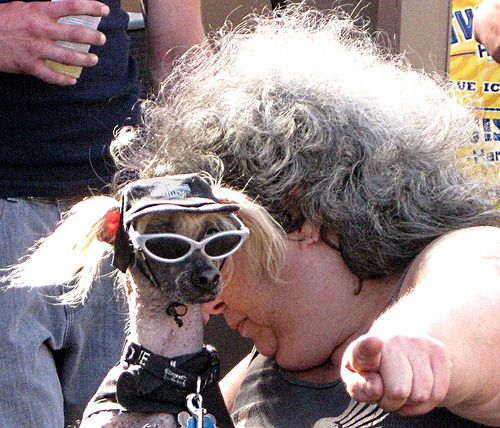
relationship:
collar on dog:
[106, 346, 237, 408] [41, 116, 292, 427]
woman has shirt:
[171, 15, 456, 414] [231, 339, 383, 427]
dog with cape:
[41, 116, 292, 427] [67, 334, 121, 411]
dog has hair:
[41, 116, 292, 427] [274, 66, 333, 139]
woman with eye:
[171, 15, 456, 414] [217, 218, 262, 262]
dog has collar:
[41, 116, 292, 427] [106, 346, 237, 408]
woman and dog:
[171, 15, 456, 414] [41, 116, 292, 427]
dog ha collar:
[41, 116, 292, 427] [106, 346, 237, 408]